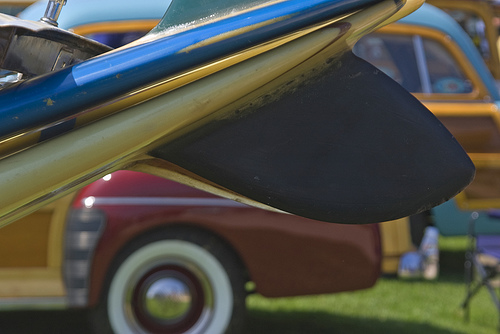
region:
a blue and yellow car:
[373, 3, 498, 259]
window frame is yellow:
[374, 19, 491, 111]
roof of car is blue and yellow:
[399, 0, 483, 42]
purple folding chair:
[459, 203, 499, 321]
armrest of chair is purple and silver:
[459, 200, 498, 321]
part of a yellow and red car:
[0, 164, 399, 332]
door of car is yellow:
[0, 196, 66, 283]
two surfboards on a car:
[1, 1, 489, 239]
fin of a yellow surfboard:
[136, 36, 486, 233]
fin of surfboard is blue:
[151, 46, 498, 236]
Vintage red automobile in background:
[80, 163, 438, 328]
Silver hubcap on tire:
[128, 267, 183, 328]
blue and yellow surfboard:
[5, 1, 473, 267]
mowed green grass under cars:
[262, 265, 496, 323]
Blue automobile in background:
[402, 20, 499, 241]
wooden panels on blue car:
[439, 97, 495, 202]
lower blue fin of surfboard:
[212, 42, 499, 267]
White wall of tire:
[88, 228, 230, 333]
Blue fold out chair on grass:
[455, 206, 498, 302]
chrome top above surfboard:
[7, 11, 84, 55]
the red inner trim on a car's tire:
[135, 265, 206, 329]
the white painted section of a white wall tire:
[137, 249, 194, 264]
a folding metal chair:
[464, 211, 498, 308]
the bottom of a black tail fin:
[175, 78, 480, 242]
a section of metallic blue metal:
[77, 54, 127, 97]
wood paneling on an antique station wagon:
[450, 106, 493, 151]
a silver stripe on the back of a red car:
[104, 177, 164, 217]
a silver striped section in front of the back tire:
[67, 207, 101, 307]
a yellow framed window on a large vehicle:
[457, 5, 496, 52]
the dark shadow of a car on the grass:
[296, 302, 396, 330]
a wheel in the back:
[87, 216, 254, 332]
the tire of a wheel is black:
[87, 217, 259, 332]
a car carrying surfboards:
[4, 3, 492, 244]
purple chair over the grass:
[456, 205, 498, 321]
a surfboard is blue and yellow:
[5, 5, 313, 68]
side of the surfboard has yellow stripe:
[116, 10, 298, 87]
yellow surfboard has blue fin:
[89, 36, 483, 231]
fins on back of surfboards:
[147, 0, 493, 231]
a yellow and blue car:
[399, 6, 498, 196]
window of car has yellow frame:
[384, 19, 496, 104]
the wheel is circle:
[114, 240, 257, 332]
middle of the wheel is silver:
[139, 283, 206, 317]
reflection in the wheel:
[139, 272, 231, 332]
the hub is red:
[231, 190, 376, 300]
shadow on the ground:
[254, 299, 442, 320]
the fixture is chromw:
[45, 60, 377, 175]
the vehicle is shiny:
[73, 187, 389, 311]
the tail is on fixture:
[130, 56, 485, 254]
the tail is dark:
[195, 80, 481, 198]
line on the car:
[81, 182, 251, 236]